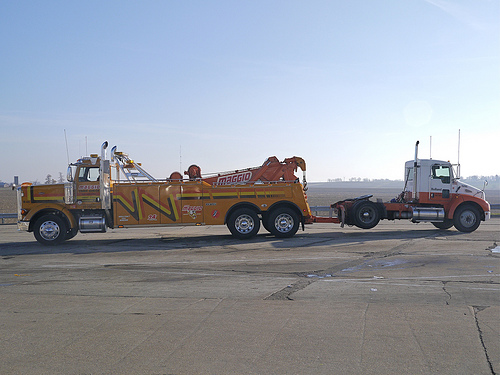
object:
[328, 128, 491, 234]
cab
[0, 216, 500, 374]
road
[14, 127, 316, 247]
tow truck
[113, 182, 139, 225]
stripes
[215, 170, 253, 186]
name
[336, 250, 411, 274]
puddle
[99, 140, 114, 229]
pipes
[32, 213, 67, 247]
hubcaps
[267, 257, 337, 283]
crack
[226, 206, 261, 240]
tires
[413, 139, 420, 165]
exhaust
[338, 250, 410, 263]
water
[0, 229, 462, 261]
shadows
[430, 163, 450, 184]
window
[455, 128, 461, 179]
antenna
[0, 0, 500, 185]
sky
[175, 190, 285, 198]
lines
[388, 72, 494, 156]
sun